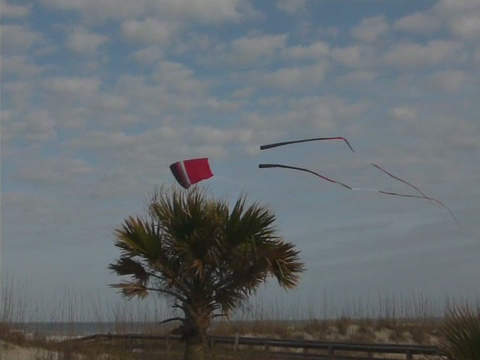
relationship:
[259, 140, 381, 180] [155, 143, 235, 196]
tail on kite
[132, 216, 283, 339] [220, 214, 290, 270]
tree has fonds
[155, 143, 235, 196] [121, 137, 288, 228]
kite in air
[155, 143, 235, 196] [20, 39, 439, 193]
kite in sky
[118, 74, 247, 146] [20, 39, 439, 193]
clouds in sky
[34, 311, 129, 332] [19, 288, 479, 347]
water at beach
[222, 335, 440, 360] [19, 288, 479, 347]
rail by beach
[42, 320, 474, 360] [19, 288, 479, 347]
grass on beach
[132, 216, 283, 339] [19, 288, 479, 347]
tree at beach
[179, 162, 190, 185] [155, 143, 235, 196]
stripe on kite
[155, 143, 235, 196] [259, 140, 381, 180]
kite has tail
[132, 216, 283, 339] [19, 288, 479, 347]
tree on beach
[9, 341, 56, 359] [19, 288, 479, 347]
sand on beach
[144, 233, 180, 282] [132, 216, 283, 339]
leaves on tree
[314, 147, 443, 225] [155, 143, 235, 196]
streamers on kite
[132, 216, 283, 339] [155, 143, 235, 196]
tree below kite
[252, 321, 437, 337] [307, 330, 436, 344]
pathway over dune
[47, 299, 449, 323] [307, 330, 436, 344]
ocean side of dune